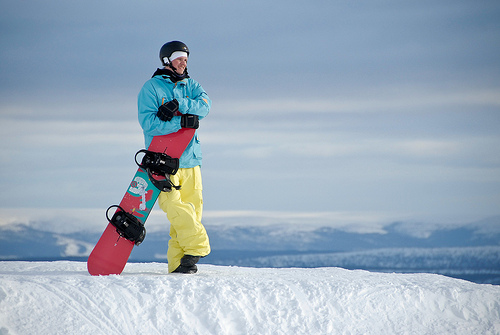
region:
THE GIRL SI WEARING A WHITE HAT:
[158, 43, 189, 69]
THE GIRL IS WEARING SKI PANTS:
[138, 148, 215, 278]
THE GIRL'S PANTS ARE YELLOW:
[150, 145, 220, 276]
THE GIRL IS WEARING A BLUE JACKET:
[129, 58, 217, 176]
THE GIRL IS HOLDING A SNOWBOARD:
[132, 60, 215, 175]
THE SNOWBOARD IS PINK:
[74, 106, 204, 292]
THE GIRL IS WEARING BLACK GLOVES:
[153, 96, 213, 143]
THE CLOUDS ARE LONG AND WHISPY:
[3, 82, 498, 207]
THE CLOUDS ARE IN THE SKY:
[0, 86, 499, 191]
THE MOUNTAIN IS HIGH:
[1, 251, 499, 333]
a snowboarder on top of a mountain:
[13, 5, 490, 332]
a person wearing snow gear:
[129, 32, 234, 306]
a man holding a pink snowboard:
[84, 24, 214, 297]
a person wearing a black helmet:
[148, 28, 206, 90]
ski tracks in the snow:
[6, 271, 159, 334]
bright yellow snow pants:
[150, 161, 222, 272]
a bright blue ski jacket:
[126, 74, 220, 174]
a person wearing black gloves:
[158, 98, 208, 136]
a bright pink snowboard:
[76, 112, 191, 282]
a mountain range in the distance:
[5, 215, 496, 275]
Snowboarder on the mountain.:
[80, 33, 213, 282]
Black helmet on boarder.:
[157, 38, 189, 75]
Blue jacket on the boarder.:
[136, 73, 210, 168]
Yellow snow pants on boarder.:
[152, 164, 214, 271]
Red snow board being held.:
[83, 110, 193, 275]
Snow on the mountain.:
[1, 253, 498, 333]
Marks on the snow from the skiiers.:
[25, 271, 487, 333]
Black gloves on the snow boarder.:
[158, 98, 205, 128]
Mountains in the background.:
[4, 205, 499, 277]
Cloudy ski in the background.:
[2, 6, 493, 218]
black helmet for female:
[156, 36, 191, 61]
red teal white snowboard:
[80, 112, 202, 264]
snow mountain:
[273, 250, 373, 330]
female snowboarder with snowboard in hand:
[99, 35, 242, 274]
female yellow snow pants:
[148, 162, 220, 273]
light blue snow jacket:
[125, 70, 225, 175]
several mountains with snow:
[306, 202, 442, 274]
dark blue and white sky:
[267, 42, 447, 189]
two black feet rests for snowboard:
[100, 140, 180, 237]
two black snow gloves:
[153, 102, 213, 142]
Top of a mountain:
[0, 147, 444, 332]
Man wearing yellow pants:
[136, 156, 226, 279]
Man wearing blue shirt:
[122, 46, 244, 181]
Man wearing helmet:
[145, 27, 212, 82]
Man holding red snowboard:
[77, 105, 216, 284]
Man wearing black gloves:
[146, 90, 214, 147]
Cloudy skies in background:
[221, 16, 491, 210]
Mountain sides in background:
[0, 135, 497, 282]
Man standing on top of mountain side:
[66, 28, 262, 293]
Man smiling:
[67, 26, 259, 290]